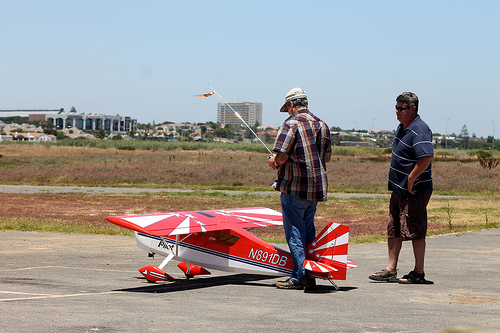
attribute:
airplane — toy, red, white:
[108, 190, 396, 302]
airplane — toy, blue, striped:
[113, 196, 379, 322]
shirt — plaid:
[263, 115, 347, 209]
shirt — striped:
[378, 112, 461, 199]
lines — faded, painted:
[20, 278, 116, 317]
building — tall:
[214, 98, 262, 134]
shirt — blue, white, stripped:
[392, 125, 433, 187]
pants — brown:
[390, 184, 427, 234]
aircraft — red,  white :
[98, 200, 362, 317]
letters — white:
[242, 244, 294, 263]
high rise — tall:
[212, 98, 265, 146]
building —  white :
[52, 124, 129, 134]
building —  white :
[3, 96, 61, 183]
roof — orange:
[17, 134, 67, 140]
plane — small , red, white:
[104, 182, 354, 313]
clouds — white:
[25, 51, 61, 86]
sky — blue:
[52, 99, 154, 102]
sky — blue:
[13, 55, 498, 110]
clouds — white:
[332, 104, 370, 119]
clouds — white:
[92, 59, 129, 93]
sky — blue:
[164, 100, 231, 107]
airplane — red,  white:
[94, 195, 358, 289]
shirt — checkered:
[284, 111, 322, 183]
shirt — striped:
[392, 159, 434, 179]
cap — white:
[275, 100, 312, 110]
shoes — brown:
[362, 263, 438, 283]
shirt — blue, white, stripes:
[392, 126, 430, 195]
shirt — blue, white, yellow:
[272, 135, 312, 181]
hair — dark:
[394, 99, 418, 109]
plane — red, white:
[105, 165, 348, 300]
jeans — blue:
[288, 194, 319, 276]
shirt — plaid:
[294, 120, 329, 183]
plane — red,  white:
[118, 192, 351, 313]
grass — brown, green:
[99, 133, 230, 173]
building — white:
[36, 100, 144, 143]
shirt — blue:
[386, 116, 430, 197]